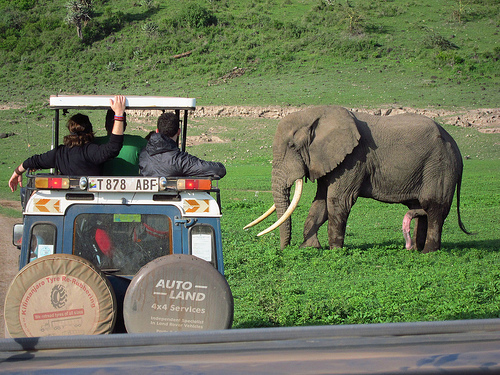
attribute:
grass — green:
[2, 67, 499, 320]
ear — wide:
[293, 107, 393, 209]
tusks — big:
[248, 185, 303, 237]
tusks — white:
[256, 177, 306, 242]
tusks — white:
[241, 203, 276, 228]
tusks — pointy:
[232, 190, 308, 249]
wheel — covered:
[4, 254, 117, 339]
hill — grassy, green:
[8, 2, 498, 107]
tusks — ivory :
[239, 194, 346, 246]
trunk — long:
[272, 142, 294, 252]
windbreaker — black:
[137, 129, 226, 178]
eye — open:
[285, 139, 303, 156]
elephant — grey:
[238, 103, 483, 260]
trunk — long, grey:
[267, 147, 298, 254]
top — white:
[48, 90, 198, 111]